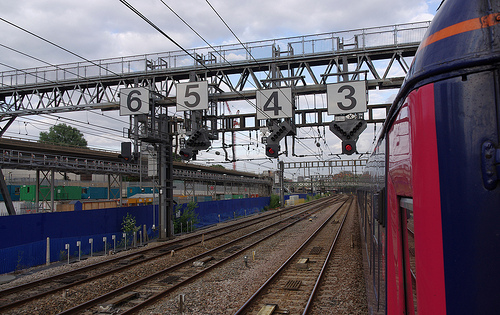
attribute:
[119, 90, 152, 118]
number — 6, six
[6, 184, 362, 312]
track — empty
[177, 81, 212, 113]
number — five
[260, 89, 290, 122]
number — four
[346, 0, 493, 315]
train — blue, red, purple, magenta, orange, pink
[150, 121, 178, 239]
pole — metal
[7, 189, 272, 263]
fence — blue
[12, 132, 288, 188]
bridge — metallic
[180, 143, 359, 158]
lights — red, on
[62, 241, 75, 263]
pole — tiny, short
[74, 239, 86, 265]
pole — tiny, short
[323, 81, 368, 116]
number — three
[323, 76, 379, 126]
sign — white, black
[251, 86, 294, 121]
sign — white, black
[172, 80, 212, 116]
sign — white, black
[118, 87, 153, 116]
sign — white, black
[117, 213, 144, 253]
plant — green